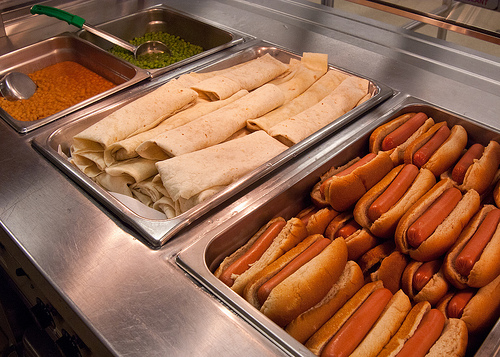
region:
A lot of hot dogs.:
[201, 104, 498, 354]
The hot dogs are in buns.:
[203, 100, 498, 355]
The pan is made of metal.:
[204, 100, 496, 355]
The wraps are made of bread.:
[49, 41, 380, 227]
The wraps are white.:
[49, 44, 381, 221]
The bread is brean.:
[205, 103, 498, 355]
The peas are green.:
[81, 11, 228, 68]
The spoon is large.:
[28, 0, 174, 62]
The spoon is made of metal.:
[31, 1, 176, 66]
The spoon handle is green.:
[29, 3, 171, 65]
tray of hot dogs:
[220, 87, 495, 354]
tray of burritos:
[56, 40, 376, 224]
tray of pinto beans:
[1, 32, 130, 132]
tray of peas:
[72, 5, 243, 77]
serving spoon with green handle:
[24, 0, 171, 68]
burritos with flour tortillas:
[31, 42, 377, 219]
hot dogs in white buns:
[180, 97, 497, 355]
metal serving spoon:
[24, 4, 190, 67]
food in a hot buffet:
[8, 7, 498, 354]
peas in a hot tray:
[23, 6, 232, 76]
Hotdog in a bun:
[212, 214, 306, 283]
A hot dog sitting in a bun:
[257, 233, 329, 300]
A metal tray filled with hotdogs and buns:
[176, 95, 499, 355]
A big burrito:
[152, 131, 284, 199]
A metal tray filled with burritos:
[32, 39, 389, 247]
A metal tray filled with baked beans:
[0, 32, 148, 131]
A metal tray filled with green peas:
[73, 1, 246, 72]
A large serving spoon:
[27, 4, 171, 66]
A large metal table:
[1, 0, 497, 355]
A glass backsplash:
[339, 0, 497, 42]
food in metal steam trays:
[6, 16, 491, 342]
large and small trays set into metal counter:
[7, 5, 492, 350]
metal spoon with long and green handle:
[26, 0, 166, 61]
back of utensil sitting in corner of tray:
[0, 51, 40, 102]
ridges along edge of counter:
[275, 5, 495, 75]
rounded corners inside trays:
[135, 166, 235, 276]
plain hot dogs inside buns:
[262, 180, 492, 347]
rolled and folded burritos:
[117, 51, 322, 156]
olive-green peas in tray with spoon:
[116, 25, 191, 66]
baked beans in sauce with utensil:
[10, 53, 110, 109]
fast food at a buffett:
[84, 74, 481, 307]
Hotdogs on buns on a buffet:
[292, 152, 492, 354]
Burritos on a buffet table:
[60, 72, 348, 223]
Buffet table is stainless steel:
[33, 211, 175, 326]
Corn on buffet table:
[3, 34, 127, 106]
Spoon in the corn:
[3, 58, 56, 104]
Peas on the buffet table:
[104, 2, 213, 73]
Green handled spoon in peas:
[56, 4, 172, 59]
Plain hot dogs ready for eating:
[271, 159, 422, 298]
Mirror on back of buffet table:
[431, 5, 496, 80]